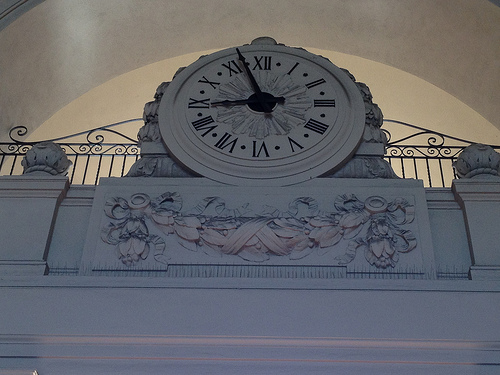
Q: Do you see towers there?
A: No, there are no towers.